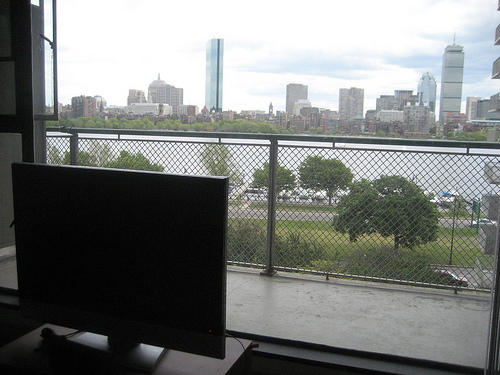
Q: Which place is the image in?
A: It is at the river.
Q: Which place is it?
A: It is a river.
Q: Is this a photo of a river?
A: Yes, it is showing a river.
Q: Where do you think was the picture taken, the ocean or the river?
A: It was taken at the river.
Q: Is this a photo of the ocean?
A: No, the picture is showing the river.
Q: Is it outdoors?
A: Yes, it is outdoors.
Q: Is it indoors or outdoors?
A: It is outdoors.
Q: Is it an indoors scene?
A: No, it is outdoors.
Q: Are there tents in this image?
A: No, there are no tents.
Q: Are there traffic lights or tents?
A: No, there are no tents or traffic lights.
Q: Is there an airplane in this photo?
A: No, there are no airplanes.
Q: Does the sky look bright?
A: Yes, the sky is bright.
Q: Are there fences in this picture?
A: Yes, there is a fence.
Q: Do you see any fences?
A: Yes, there is a fence.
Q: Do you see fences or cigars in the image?
A: Yes, there is a fence.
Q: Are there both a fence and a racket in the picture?
A: No, there is a fence but no rackets.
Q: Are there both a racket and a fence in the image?
A: No, there is a fence but no rackets.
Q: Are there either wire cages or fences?
A: Yes, there is a wire fence.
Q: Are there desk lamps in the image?
A: No, there are no desk lamps.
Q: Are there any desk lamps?
A: No, there are no desk lamps.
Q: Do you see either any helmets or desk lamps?
A: No, there are no desk lamps or helmets.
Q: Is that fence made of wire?
A: Yes, the fence is made of wire.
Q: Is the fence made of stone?
A: No, the fence is made of wire.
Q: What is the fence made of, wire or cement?
A: The fence is made of wire.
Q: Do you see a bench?
A: No, there are no benches.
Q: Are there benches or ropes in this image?
A: No, there are no benches or ropes.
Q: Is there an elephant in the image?
A: No, there are no elephants.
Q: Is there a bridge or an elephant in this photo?
A: No, there are no elephants or bridges.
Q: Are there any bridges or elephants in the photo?
A: No, there are no elephants or bridges.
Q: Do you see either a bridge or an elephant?
A: No, there are no elephants or bridges.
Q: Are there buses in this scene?
A: No, there are no buses.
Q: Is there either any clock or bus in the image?
A: No, there are no buses or clocks.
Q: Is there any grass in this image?
A: Yes, there is grass.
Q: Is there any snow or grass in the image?
A: Yes, there is grass.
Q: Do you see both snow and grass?
A: No, there is grass but no snow.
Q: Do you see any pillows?
A: No, there are no pillows.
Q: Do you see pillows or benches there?
A: No, there are no pillows or benches.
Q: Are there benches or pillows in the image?
A: No, there are no pillows or benches.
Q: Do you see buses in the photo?
A: No, there are no buses.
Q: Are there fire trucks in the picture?
A: No, there are no fire trucks.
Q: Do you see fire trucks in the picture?
A: No, there are no fire trucks.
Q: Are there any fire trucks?
A: No, there are no fire trucks.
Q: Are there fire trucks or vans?
A: No, there are no fire trucks or vans.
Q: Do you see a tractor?
A: No, there are no tractors.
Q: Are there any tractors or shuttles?
A: No, there are no tractors or shuttles.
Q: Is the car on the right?
A: Yes, the car is on the right of the image.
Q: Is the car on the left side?
A: No, the car is on the right of the image.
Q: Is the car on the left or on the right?
A: The car is on the right of the image.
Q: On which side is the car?
A: The car is on the right of the image.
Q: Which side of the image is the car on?
A: The car is on the right of the image.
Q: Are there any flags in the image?
A: No, there are no flags.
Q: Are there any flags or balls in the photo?
A: No, there are no flags or balls.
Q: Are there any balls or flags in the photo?
A: No, there are no flags or balls.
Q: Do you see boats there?
A: Yes, there is a boat.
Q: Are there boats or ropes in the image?
A: Yes, there is a boat.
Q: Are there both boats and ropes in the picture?
A: No, there is a boat but no ropes.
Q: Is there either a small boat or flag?
A: Yes, there is a small boat.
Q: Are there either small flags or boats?
A: Yes, there is a small boat.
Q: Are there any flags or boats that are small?
A: Yes, the boat is small.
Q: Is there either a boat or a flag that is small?
A: Yes, the boat is small.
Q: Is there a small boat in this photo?
A: Yes, there is a small boat.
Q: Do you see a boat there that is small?
A: Yes, there is a boat that is small.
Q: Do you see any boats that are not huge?
A: Yes, there is a small boat.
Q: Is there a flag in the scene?
A: No, there are no flags.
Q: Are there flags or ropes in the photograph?
A: No, there are no flags or ropes.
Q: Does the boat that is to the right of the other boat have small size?
A: Yes, the boat is small.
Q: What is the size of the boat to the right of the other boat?
A: The boat is small.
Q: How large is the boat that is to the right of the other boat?
A: The boat is small.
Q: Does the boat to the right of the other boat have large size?
A: No, the boat is small.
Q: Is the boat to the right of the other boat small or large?
A: The boat is small.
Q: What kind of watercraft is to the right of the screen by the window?
A: The watercraft is a boat.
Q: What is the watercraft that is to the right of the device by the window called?
A: The watercraft is a boat.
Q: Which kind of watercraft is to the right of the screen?
A: The watercraft is a boat.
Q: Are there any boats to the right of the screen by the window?
A: Yes, there is a boat to the right of the screen.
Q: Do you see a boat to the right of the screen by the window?
A: Yes, there is a boat to the right of the screen.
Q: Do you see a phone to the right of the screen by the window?
A: No, there is a boat to the right of the screen.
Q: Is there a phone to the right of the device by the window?
A: No, there is a boat to the right of the screen.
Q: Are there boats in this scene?
A: Yes, there is a boat.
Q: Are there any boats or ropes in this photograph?
A: Yes, there is a boat.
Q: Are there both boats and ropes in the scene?
A: No, there is a boat but no ropes.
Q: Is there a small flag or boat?
A: Yes, there is a small boat.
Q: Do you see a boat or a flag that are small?
A: Yes, the boat is small.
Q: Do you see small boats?
A: Yes, there is a small boat.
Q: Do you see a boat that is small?
A: Yes, there is a boat that is small.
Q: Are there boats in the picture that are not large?
A: Yes, there is a small boat.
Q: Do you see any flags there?
A: No, there are no flags.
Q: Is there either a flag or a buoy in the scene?
A: No, there are no flags or buoys.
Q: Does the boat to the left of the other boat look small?
A: Yes, the boat is small.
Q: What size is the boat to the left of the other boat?
A: The boat is small.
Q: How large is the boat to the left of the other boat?
A: The boat is small.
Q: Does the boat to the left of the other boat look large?
A: No, the boat is small.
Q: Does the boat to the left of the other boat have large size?
A: No, the boat is small.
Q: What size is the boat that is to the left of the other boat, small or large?
A: The boat is small.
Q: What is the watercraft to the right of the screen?
A: The watercraft is a boat.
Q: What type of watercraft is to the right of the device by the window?
A: The watercraft is a boat.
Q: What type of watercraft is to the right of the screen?
A: The watercraft is a boat.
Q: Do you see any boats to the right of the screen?
A: Yes, there is a boat to the right of the screen.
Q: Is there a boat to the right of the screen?
A: Yes, there is a boat to the right of the screen.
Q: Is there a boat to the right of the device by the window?
A: Yes, there is a boat to the right of the screen.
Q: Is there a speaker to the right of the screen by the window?
A: No, there is a boat to the right of the screen.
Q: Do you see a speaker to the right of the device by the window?
A: No, there is a boat to the right of the screen.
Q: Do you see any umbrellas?
A: No, there are no umbrellas.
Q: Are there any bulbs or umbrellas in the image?
A: No, there are no umbrellas or bulbs.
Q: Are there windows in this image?
A: Yes, there is a window.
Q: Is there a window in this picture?
A: Yes, there is a window.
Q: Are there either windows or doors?
A: Yes, there is a window.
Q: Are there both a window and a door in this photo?
A: No, there is a window but no doors.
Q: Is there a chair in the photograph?
A: No, there are no chairs.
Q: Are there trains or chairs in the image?
A: No, there are no chairs or trains.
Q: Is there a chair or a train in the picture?
A: No, there are no chairs or trains.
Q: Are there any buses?
A: No, there are no buses.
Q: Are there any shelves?
A: No, there are no shelves.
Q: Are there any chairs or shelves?
A: No, there are no shelves or chairs.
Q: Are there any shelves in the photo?
A: No, there are no shelves.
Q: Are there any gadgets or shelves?
A: No, there are no shelves or gadgets.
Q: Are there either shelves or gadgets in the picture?
A: No, there are no shelves or gadgets.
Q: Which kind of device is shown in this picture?
A: The device is a screen.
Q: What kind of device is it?
A: The device is a screen.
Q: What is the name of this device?
A: This is a screen.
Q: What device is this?
A: This is a screen.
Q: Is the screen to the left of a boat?
A: Yes, the screen is to the left of a boat.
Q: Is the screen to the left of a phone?
A: No, the screen is to the left of a boat.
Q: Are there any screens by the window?
A: Yes, there is a screen by the window.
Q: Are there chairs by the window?
A: No, there is a screen by the window.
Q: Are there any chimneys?
A: No, there are no chimneys.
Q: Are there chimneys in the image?
A: No, there are no chimneys.